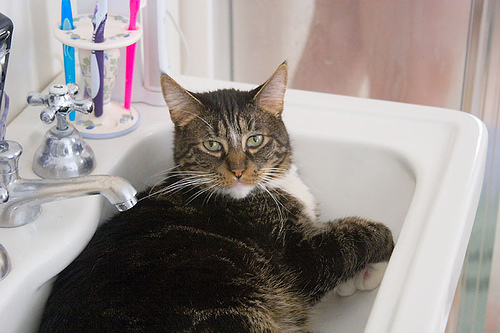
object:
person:
[288, 2, 470, 104]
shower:
[208, 1, 488, 114]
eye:
[246, 134, 263, 147]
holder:
[55, 11, 145, 137]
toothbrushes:
[60, 0, 74, 120]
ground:
[315, 160, 352, 190]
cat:
[35, 59, 394, 331]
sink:
[0, 72, 490, 331]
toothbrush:
[95, 0, 107, 116]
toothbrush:
[124, 0, 137, 107]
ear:
[159, 71, 206, 126]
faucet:
[0, 140, 139, 228]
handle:
[27, 73, 95, 122]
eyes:
[202, 140, 221, 152]